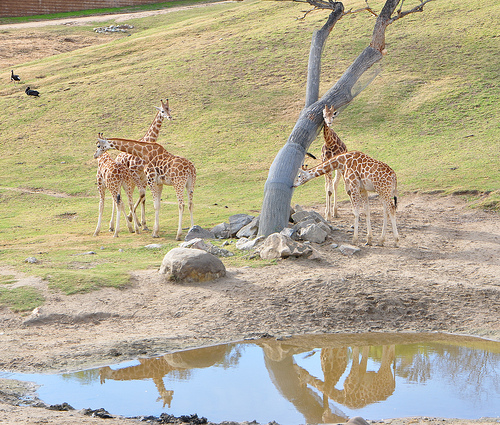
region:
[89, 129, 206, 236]
a giraffe standing near another giraffe.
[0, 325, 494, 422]
a reflecting pool of water.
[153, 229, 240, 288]
a rock near a pond.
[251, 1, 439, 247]
a tree near a rock.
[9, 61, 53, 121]
a plant on a hill.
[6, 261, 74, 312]
a patch of brown dirt.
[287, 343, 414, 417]
a reflection of a giraffe.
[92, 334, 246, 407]
a giraffe's brown reflection.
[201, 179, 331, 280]
rocks around the base of a tree.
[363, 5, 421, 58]
a section of a tree.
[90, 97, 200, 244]
three giraffe standing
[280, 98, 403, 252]
two girraffe next to tree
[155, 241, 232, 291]
large rock sticking out of ground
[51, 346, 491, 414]
muddy pool of water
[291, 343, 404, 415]
reflection of giraffe in pool of water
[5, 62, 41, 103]
black birds in background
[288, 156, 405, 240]
giraffe with head bowed toward tree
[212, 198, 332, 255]
rocks around base of tree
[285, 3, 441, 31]
branches of tree stripped of leaves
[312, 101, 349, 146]
giraffe rubbing neck against tree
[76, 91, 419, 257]
Five giraffes close to a tree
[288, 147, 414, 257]
giraffe has neck low in the tree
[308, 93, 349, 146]
neck of giraffe is touching the tree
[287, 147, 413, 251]
giraffe if facing to the left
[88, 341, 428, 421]
giraffes are reflected in the water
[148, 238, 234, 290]
big stone near a tree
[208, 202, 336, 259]
several stones surround the tree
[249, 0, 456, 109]
a tree without leaves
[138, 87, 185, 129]
giraffe has horns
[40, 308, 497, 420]
small waterhole next to five giraffes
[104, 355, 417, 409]
giraffes reflected in the water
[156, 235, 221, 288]
a large gray rock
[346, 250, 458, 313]
beige sand on the ground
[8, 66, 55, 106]
black birds resting on the grass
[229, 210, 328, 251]
a pile of rocks around the tree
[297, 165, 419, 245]
a giraffe licking the tree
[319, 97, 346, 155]
a giraffe scratching itself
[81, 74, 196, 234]
two giraffes walking in the pasture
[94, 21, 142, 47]
a circle of gray stones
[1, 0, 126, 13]
a red brick wall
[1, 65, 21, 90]
a [male] ostrich gallivanting in the distance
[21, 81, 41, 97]
another, indeterminate, large black bird sits beside gallivanting ostrich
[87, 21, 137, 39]
a circle of rocks, perhaps, far away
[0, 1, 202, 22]
a long strip of lawnlike green grass beside a brick wall in the distance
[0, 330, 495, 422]
giraffesw, trees, & elsewise invisible grasses reflected in the pond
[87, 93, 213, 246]
big giraffe, smaller giraffe, smallest giraffe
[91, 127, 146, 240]
smallest giraffe, juvenile giraffe, has hidden head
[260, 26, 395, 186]
tree wears wire armoured sock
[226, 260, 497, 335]
the footprints of many animals in the mud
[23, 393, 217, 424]
dark rocks @ the shoreline across the pond